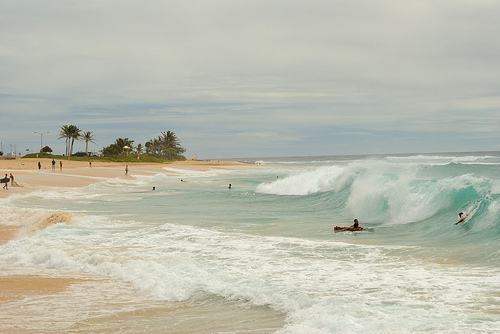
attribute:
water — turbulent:
[146, 138, 498, 266]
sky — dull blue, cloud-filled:
[12, 19, 263, 148]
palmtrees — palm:
[57, 120, 97, 166]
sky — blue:
[257, 62, 399, 143]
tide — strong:
[114, 222, 388, 309]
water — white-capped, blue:
[284, 151, 474, 248]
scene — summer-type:
[11, 0, 496, 328]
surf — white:
[259, 172, 339, 190]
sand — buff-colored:
[4, 160, 177, 330]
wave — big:
[254, 156, 484, 240]